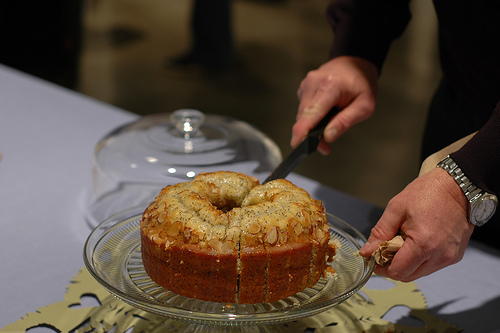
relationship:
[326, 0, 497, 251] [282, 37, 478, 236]
person wearing shirt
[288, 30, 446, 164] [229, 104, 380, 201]
person holding knife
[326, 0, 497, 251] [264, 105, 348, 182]
person using knife